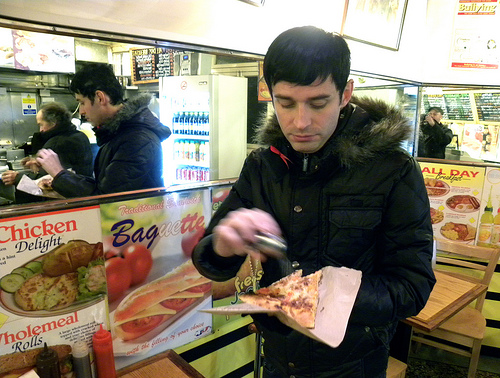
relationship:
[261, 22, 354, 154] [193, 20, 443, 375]
head of person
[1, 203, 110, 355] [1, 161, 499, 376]
sign on wall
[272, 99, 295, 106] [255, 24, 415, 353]
eye on person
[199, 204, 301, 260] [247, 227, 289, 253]
hand shaking spice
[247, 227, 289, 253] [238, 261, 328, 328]
spice on pizza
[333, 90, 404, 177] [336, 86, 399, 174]
fur on hood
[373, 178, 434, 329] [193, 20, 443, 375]
arm of person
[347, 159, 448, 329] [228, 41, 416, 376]
arm of person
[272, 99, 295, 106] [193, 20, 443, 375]
eye of person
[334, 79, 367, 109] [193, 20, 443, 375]
ear of person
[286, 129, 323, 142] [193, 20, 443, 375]
mouth of person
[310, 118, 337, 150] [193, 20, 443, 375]
jaw of person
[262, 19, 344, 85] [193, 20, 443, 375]
hair of person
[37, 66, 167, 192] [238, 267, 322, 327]
man eating pizza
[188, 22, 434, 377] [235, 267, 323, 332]
someone eating pizza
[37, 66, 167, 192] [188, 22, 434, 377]
man photographing someone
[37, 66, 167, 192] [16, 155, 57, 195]
man eating pizza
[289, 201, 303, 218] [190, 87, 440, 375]
button on jacket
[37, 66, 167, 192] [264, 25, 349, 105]
man has black hair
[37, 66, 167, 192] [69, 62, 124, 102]
man has black hair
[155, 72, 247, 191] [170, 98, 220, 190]
cooler full of drinks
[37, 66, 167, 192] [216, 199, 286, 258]
man has hands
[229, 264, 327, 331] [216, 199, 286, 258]
pizza held in hands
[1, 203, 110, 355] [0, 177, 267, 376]
sign on wall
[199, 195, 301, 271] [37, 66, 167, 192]
hand of man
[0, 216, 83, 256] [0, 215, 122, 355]
words on sign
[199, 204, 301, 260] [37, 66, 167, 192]
hand of man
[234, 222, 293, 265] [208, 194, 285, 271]
shaker in hand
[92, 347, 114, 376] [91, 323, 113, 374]
ketchup in bottle